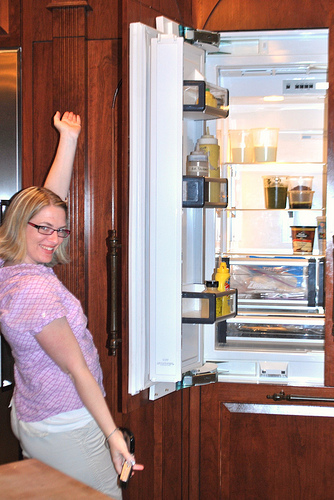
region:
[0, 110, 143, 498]
woman is posing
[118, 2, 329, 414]
refrigerator is open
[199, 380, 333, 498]
lower cabinet door is closed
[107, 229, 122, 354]
large handle on refrigerator door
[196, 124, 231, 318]
multiple bottles of mustard on refrigerator door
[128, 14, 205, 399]
inside of refrigerator door is white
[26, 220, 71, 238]
woman wearing glasses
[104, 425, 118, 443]
woman wearing thin bracelet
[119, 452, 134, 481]
woman holding item in hand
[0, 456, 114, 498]
wooden counter in front of woman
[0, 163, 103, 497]
young woman wearing glasses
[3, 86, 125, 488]
young woman with arm in the air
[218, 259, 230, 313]
Frenches mustard on bottom shelf of refrigerator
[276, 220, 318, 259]
salsa on bottom shelf inside refrigerator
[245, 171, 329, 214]
plastic storage containers on middle shelf of refrigerator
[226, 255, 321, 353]
lunch meat in drawer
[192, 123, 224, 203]
bottles of sauce on second shelf of door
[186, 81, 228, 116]
lemon juice in top shelf of door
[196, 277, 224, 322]
dijon mustard on bottom shelf of door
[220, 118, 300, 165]
plastic containers on top shelf of refrigerator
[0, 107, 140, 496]
woman posing in front of a refrigerator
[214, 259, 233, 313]
mustard bottle on the side shelf in the refrigerator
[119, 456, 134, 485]
silver item in the woman's right hand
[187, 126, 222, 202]
squeeze bottles on the side shelf of the refrigerator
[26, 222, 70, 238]
eye glasses on the woman's face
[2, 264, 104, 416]
purple blouse on the woman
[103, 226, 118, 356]
handle on the refrigerator door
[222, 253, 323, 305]
refrigerator drawer with clear window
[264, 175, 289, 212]
plastic cup with liquid item in it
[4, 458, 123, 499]
brown table next to the woman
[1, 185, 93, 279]
human female smiling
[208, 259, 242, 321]
plastic bottle filled with yellow mustard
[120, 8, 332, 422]
built in refrigerator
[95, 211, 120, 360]
wooden door handle for cabinet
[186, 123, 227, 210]
homemade bottled condiments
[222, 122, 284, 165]
leftovers stored in refrigerator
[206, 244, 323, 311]
crisper drawer of refrigerator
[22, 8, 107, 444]
natural wood paneling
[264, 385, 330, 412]
metal door handle for a cabinet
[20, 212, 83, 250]
eyeglasses with plastic frames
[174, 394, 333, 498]
a brown maple cabinet.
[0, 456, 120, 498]
a brown wooden stand.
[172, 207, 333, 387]
a refrigerator with food.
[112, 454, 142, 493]
a woman is holding a phone.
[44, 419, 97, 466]
a woman is wearing beige shorts.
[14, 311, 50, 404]
a woman is wearing a pink and white shirt.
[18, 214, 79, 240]
a woman is wearing glasses.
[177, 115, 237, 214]
a shelf in the refrigerator with mustard.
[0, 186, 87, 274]
a woman is smiling.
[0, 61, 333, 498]
a woman is showing off the refrigerator.